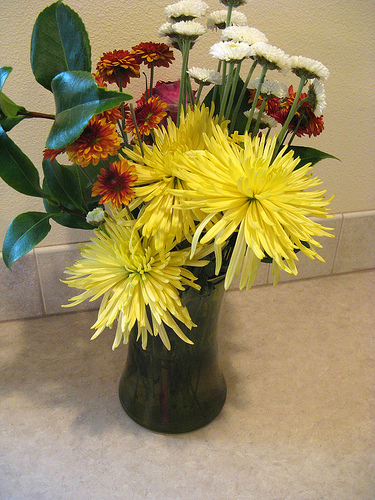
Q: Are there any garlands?
A: No, there are no garlands.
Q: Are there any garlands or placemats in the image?
A: No, there are no garlands or placemats.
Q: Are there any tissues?
A: No, there are no tissues.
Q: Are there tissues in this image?
A: No, there are no tissues.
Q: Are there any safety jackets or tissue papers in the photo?
A: No, there are no tissue papers or safety jackets.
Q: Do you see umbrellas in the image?
A: No, there are no umbrellas.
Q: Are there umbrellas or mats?
A: No, there are no umbrellas or mats.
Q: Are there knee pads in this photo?
A: No, there are no knee pads.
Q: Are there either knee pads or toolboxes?
A: No, there are no knee pads or toolboxes.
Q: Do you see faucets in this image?
A: No, there are no faucets.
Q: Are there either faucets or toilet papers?
A: No, there are no faucets or toilet papers.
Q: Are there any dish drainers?
A: No, there are no dish drainers.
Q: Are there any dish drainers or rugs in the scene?
A: No, there are no dish drainers or rugs.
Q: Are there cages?
A: No, there are no cages.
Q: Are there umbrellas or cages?
A: No, there are no cages or umbrellas.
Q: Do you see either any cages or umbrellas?
A: No, there are no cages or umbrellas.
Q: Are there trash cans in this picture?
A: No, there are no trash cans.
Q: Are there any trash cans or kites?
A: No, there are no trash cans or kites.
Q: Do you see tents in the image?
A: No, there are no tents.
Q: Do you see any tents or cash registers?
A: No, there are no tents or cash registers.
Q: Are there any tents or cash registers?
A: No, there are no tents or cash registers.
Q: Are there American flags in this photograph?
A: No, there are no American flags.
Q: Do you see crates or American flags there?
A: No, there are no American flags or crates.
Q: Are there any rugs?
A: No, there are no rugs.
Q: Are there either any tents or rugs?
A: No, there are no rugs or tents.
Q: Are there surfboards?
A: No, there are no surfboards.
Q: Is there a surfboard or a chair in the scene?
A: No, there are no surfboards or chairs.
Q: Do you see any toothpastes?
A: No, there are no toothpastes.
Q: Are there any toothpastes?
A: No, there are no toothpastes.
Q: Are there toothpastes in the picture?
A: No, there are no toothpastes.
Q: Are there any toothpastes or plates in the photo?
A: No, there are no toothpastes or plates.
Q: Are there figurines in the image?
A: No, there are no figurines.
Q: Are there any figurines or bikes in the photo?
A: No, there are no figurines or bikes.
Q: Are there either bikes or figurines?
A: No, there are no figurines or bikes.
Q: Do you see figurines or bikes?
A: No, there are no figurines or bikes.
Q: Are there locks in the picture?
A: No, there are no locks.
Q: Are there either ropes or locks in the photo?
A: No, there are no locks or ropes.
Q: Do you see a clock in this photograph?
A: No, there are no clocks.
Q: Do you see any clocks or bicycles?
A: No, there are no clocks or bicycles.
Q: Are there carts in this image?
A: No, there are no carts.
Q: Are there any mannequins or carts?
A: No, there are no carts or mannequins.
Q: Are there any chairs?
A: No, there are no chairs.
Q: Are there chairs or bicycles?
A: No, there are no chairs or bicycles.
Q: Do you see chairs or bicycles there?
A: No, there are no chairs or bicycles.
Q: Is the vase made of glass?
A: Yes, the vase is made of glass.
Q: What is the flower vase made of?
A: The vase is made of glass.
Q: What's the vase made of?
A: The vase is made of glass.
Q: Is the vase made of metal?
A: No, the vase is made of glass.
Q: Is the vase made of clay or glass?
A: The vase is made of glass.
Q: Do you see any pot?
A: No, there are no pots.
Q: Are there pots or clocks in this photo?
A: No, there are no pots or clocks.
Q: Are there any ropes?
A: No, there are no ropes.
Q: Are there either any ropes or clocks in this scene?
A: No, there are no ropes or clocks.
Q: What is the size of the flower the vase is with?
A: The flower is small.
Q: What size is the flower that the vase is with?
A: The flower is small.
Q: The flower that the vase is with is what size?
A: The flower is small.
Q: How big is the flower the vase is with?
A: The flower is small.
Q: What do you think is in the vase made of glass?
A: The flower is in the vase.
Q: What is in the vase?
A: The flower is in the vase.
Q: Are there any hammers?
A: No, there are no hammers.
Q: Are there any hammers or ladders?
A: No, there are no hammers or ladders.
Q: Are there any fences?
A: No, there are no fences.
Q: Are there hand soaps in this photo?
A: No, there are no hand soaps.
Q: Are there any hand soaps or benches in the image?
A: No, there are no hand soaps or benches.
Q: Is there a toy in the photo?
A: No, there are no toys.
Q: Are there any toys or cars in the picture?
A: No, there are no toys or cars.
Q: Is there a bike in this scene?
A: No, there are no bikes.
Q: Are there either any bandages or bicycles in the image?
A: No, there are no bicycles or bandages.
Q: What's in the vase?
A: The flower is in the vase.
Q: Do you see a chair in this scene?
A: No, there are no chairs.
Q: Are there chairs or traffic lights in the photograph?
A: No, there are no chairs or traffic lights.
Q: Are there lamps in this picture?
A: No, there are no lamps.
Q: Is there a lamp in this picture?
A: No, there are no lamps.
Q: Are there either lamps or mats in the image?
A: No, there are no lamps or mats.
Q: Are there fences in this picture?
A: No, there are no fences.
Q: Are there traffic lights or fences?
A: No, there are no fences or traffic lights.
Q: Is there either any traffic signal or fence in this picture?
A: No, there are no fences or traffic lights.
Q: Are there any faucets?
A: No, there are no faucets.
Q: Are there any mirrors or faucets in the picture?
A: No, there are no faucets or mirrors.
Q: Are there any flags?
A: No, there are no flags.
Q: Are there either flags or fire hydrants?
A: No, there are no flags or fire hydrants.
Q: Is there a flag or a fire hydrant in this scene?
A: No, there are no flags or fire hydrants.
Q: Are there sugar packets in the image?
A: No, there are no sugar packets.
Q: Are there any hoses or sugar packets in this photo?
A: No, there are no sugar packets or hoses.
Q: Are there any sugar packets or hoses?
A: No, there are no sugar packets or hoses.